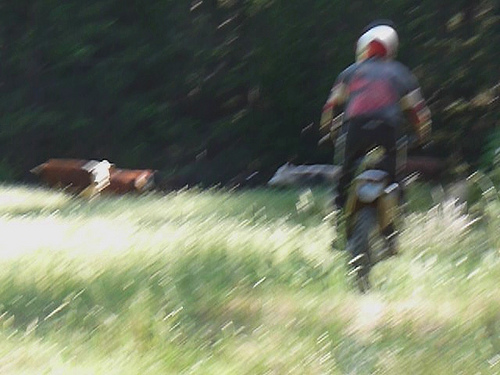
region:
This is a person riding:
[311, 22, 450, 312]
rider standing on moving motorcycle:
[310, 21, 431, 290]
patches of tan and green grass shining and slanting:
[10, 185, 492, 367]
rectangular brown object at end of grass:
[26, 152, 156, 207]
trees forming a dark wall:
[0, 1, 495, 183]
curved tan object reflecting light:
[75, 157, 110, 203]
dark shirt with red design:
[326, 55, 418, 120]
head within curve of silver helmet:
[352, 20, 392, 60]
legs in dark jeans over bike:
[330, 116, 400, 218]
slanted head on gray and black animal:
[265, 160, 337, 187]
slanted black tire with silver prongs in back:
[340, 197, 375, 293]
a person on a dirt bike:
[295, 8, 451, 303]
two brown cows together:
[31, 138, 186, 228]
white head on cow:
[84, 153, 117, 200]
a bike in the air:
[310, 121, 447, 312]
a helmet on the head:
[348, 13, 407, 65]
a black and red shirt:
[333, 54, 431, 129]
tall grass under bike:
[54, 183, 497, 351]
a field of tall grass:
[1, 149, 496, 371]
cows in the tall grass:
[19, 133, 189, 251]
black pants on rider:
[311, 102, 456, 259]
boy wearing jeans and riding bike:
[318, 24, 430, 223]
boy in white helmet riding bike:
[355, 20, 403, 62]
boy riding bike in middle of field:
[341, 145, 410, 293]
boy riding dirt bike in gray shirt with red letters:
[332, 59, 422, 123]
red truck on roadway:
[37, 148, 152, 191]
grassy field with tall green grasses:
[3, 165, 493, 370]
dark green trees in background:
[6, 5, 496, 186]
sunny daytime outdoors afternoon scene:
[8, 5, 493, 365]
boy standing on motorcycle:
[316, 17, 441, 230]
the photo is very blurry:
[0, 0, 499, 371]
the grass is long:
[3, 176, 499, 371]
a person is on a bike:
[324, 27, 428, 292]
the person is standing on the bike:
[324, 28, 430, 287]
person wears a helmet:
[357, 23, 400, 64]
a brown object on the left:
[36, 158, 153, 195]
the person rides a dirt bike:
[333, 171, 404, 286]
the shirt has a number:
[353, 75, 389, 122]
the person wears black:
[333, 122, 413, 203]